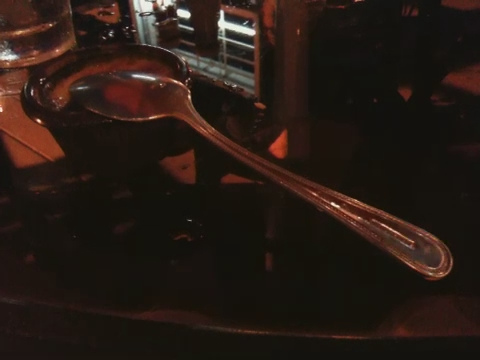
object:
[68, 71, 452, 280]
spoon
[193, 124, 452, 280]
handle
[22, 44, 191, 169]
bowl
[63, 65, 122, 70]
sauce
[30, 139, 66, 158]
table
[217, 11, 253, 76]
racks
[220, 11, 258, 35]
frame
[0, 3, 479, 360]
place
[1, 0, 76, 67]
water can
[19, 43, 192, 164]
cup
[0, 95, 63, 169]
dining table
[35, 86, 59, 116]
dish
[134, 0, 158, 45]
glass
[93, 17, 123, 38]
corner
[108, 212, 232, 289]
countertop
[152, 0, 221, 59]
display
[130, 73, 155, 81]
reflection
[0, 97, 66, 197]
counter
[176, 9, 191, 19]
light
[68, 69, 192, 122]
spoonhead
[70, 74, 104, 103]
tarnish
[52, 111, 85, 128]
edge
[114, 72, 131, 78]
spots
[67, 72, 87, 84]
cream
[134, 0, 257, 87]
window